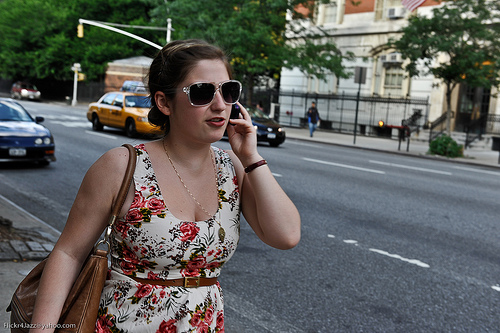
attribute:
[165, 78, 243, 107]
sunglasses — very dark, modern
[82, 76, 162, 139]
cab — taxi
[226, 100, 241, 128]
phone — cell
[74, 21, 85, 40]
lamp — over hanging, street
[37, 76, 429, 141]
fence — traditional, iron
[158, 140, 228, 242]
necklace — gold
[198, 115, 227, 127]
lips — human, twisted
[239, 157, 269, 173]
wristband — leather, watch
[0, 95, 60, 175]
automobile — older, Lexus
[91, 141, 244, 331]
dress — floral pattern, red, white, flower print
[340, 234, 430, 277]
line — fading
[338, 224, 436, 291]
line — white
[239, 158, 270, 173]
watchband — brown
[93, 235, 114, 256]
loop — metal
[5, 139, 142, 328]
purse — large, brown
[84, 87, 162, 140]
cab — yellow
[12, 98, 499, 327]
street — city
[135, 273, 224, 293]
belt — brown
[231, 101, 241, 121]
cell phone — black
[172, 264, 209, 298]
belt — brown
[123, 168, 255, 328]
dress — white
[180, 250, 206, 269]
flowers — red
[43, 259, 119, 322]
purse — brown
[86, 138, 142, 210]
shoulder — woman's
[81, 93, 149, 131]
cab — taxi, yellow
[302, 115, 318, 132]
pants — blue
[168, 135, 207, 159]
neck — woman's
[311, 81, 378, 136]
fence — black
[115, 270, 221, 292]
belt — brown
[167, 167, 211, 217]
chain — gold, long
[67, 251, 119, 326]
purse — brown, leather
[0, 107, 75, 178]
car — parked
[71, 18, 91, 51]
signal — traffic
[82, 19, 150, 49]
arm — long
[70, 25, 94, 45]
signal — traffic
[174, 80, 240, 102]
sunglasses — clear framed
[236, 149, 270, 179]
watch — brown, leather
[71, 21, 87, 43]
light — street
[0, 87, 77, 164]
car — black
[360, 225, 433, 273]
line — white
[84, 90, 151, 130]
taxi — yellow, middle 